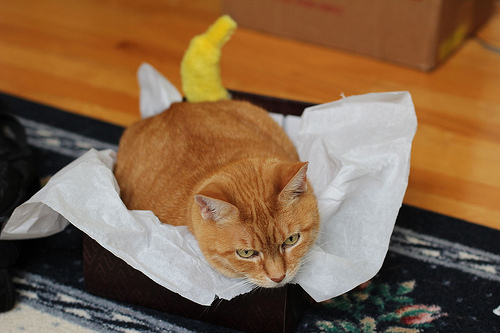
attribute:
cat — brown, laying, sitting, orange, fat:
[126, 100, 304, 251]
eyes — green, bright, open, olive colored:
[226, 236, 311, 261]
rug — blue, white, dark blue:
[1, 120, 499, 332]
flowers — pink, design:
[325, 287, 386, 332]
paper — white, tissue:
[303, 79, 408, 210]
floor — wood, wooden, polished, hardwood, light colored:
[26, 7, 494, 179]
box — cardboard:
[226, 3, 496, 57]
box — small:
[88, 251, 286, 331]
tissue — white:
[285, 90, 421, 205]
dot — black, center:
[243, 246, 250, 258]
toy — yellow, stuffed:
[174, 18, 244, 103]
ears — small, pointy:
[190, 145, 306, 211]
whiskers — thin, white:
[288, 251, 349, 293]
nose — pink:
[267, 273, 289, 285]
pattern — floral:
[335, 284, 477, 332]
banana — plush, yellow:
[181, 8, 237, 101]